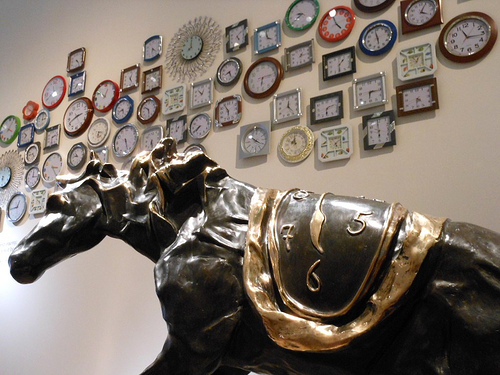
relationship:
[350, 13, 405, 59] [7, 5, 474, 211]
clock on wall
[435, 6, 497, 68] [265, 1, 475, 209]
clock on wall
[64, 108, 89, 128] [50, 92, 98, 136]
dials on a clock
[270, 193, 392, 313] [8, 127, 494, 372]
numbers on horse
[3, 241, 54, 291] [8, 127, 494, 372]
nose of horse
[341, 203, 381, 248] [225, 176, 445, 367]
5 on saddle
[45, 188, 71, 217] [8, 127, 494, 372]
eye of horse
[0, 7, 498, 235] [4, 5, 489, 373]
clocks on wall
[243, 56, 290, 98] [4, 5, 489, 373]
clock on wall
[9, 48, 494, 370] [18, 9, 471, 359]
wall in room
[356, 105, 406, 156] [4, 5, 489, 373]
clock hung on wall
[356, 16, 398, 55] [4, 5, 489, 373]
clock hung on wall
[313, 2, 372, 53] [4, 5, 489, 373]
clock hung on wall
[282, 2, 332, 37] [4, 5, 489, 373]
clock hung on wall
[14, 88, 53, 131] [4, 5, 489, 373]
clock hung on wall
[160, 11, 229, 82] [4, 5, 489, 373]
clock hung on wall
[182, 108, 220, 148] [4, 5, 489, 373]
clock hung on wall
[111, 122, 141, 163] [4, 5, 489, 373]
clock hung on wall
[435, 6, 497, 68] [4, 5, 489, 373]
clock hung on wall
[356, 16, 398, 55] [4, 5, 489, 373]
clock in front of wall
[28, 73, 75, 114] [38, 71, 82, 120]
clock in frame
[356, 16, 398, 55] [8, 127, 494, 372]
clock of horse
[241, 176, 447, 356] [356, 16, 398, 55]
clock on clock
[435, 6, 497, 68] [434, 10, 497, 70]
clock with frame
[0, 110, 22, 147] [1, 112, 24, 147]
clock with frame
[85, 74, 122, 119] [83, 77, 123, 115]
clock has frame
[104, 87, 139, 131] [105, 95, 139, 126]
clock has frame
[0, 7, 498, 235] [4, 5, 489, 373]
clocks are on a wall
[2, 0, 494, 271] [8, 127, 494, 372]
clock in back of horse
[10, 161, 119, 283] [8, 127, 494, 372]
head in horse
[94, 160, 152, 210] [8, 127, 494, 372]
mane in horse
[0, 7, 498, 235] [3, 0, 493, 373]
clocks are in room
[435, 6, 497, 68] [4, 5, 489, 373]
clock mounted to wall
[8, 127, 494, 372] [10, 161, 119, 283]
horse has head